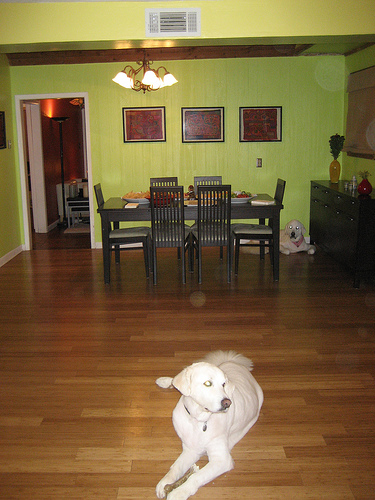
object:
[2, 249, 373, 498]
floor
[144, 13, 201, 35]
vent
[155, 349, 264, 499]
dog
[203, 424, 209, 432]
tag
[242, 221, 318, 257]
dog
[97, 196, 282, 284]
table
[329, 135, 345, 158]
plant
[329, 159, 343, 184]
vase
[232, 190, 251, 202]
food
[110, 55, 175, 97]
light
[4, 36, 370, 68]
ceiling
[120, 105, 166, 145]
art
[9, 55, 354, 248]
wall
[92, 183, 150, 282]
chair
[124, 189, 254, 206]
dinner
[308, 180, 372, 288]
hutch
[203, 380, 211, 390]
eye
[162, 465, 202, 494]
bone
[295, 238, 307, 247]
bandana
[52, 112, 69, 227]
lamp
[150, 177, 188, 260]
chair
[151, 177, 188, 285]
chair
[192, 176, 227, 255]
chair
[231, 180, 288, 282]
chair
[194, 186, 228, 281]
chair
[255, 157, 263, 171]
switch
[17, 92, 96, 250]
door